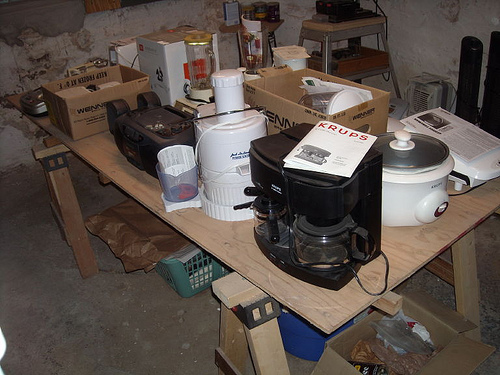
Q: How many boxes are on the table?
A: Three.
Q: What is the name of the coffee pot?
A: Krups.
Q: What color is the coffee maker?
A: Black.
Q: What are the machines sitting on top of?
A: Wooden table.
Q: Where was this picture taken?
A: Basement.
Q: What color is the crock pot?
A: White.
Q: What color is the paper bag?
A: Brown.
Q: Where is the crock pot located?
A: On the table.